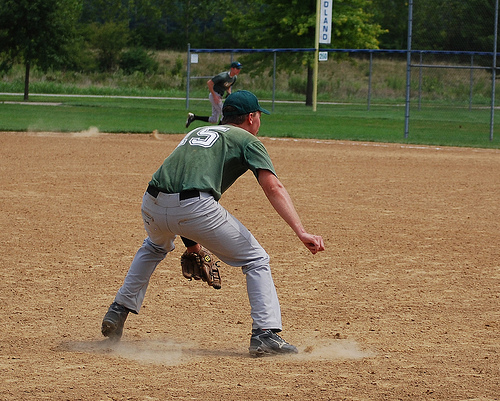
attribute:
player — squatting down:
[121, 88, 259, 329]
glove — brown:
[177, 243, 223, 290]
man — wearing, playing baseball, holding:
[97, 91, 334, 362]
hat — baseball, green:
[181, 96, 352, 141]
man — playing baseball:
[186, 59, 241, 125]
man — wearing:
[82, 93, 319, 366]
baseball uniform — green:
[117, 126, 279, 329]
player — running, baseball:
[184, 58, 244, 132]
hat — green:
[224, 88, 274, 122]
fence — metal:
[181, 40, 498, 142]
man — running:
[184, 56, 243, 131]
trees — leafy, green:
[212, 12, 368, 54]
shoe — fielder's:
[241, 323, 296, 356]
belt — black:
[134, 185, 209, 206]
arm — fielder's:
[253, 167, 328, 254]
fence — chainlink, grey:
[184, 60, 488, 142]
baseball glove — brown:
[171, 248, 231, 294]